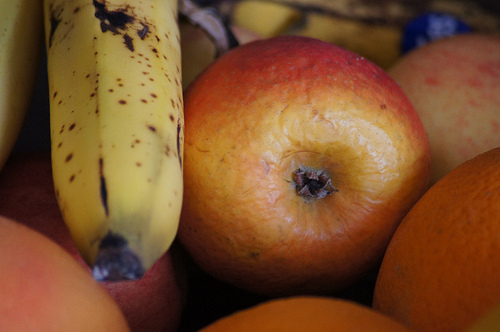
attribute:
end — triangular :
[91, 229, 159, 287]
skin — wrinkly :
[261, 75, 355, 122]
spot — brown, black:
[87, 3, 154, 53]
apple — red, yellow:
[173, 27, 436, 298]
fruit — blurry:
[2, 1, 499, 326]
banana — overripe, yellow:
[34, 1, 191, 284]